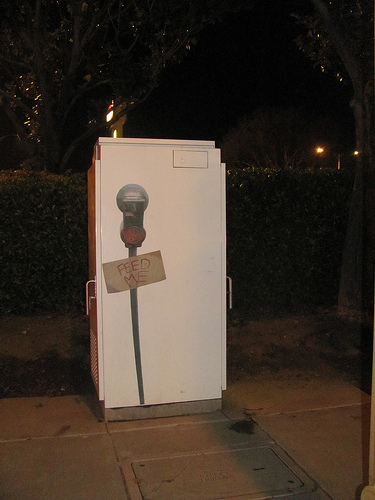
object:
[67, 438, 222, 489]
part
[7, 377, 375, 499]
path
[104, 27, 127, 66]
part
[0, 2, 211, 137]
tree branches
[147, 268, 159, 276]
part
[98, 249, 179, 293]
poster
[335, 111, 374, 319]
stem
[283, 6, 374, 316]
tree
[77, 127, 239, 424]
structure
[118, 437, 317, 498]
panel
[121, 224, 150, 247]
handle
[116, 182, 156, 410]
parking meter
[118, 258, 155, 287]
writing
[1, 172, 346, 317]
hedge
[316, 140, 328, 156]
light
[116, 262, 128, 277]
letter "f"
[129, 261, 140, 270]
letter "e"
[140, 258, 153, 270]
letter "d"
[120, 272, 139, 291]
letter "m"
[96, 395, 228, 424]
bottom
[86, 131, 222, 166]
top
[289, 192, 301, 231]
leaves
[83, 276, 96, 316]
handle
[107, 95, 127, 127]
sign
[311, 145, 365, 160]
street light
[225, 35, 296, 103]
night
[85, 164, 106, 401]
door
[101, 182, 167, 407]
cardboard